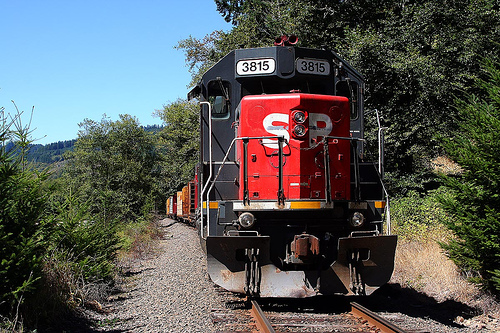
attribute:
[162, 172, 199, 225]
train cars — additional train 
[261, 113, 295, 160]
s — Two large, white Letters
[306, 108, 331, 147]
p — Two large, white Letters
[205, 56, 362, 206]
train engine — black, red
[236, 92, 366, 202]
structure —  red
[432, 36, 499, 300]
green tree — large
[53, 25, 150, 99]
sky — beautiful blue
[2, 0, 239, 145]
sky — blue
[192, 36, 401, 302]
train engine. — large train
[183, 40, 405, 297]
train — red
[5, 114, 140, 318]
trees — left.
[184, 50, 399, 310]
engine. — train 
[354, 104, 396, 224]
brush — piece 